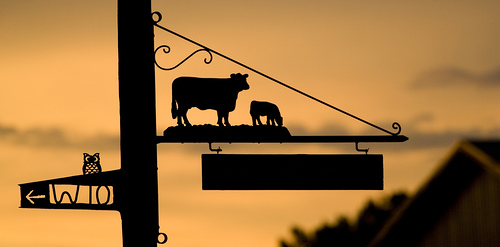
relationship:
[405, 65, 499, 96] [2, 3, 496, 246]
clouds in sky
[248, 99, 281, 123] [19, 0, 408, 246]
cow on sign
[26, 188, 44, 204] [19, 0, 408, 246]
arrow on sign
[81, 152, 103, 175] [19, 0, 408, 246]
owl on sign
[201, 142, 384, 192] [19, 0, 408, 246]
plate hanging on sign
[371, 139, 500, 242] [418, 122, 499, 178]
roof has peak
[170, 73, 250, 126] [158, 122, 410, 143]
cow on rail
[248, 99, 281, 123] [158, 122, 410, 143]
cow on rail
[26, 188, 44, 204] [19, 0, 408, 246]
arrow cut into pole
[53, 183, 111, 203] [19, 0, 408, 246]
owl cut into sign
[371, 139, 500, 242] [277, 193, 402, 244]
roof next to trees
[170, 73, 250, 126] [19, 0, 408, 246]
cow on sign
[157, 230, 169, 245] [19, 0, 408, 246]
hook on sign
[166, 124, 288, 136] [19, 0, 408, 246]
ground shape on sign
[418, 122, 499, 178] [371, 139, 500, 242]
peak of roof